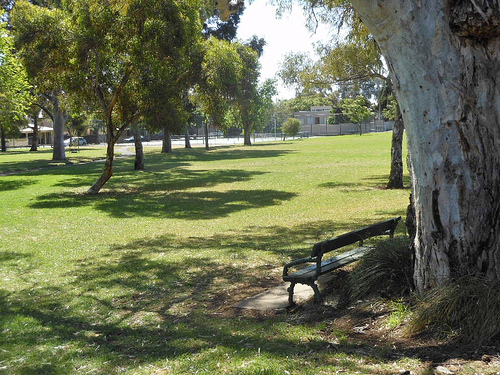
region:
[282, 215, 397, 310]
wood and wrought iron bench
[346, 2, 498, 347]
tree with white bark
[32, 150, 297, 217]
shadows cast by trees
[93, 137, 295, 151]
tennis court in the background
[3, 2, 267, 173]
clump of trees in the park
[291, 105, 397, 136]
office building in the background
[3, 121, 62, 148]
a home near the park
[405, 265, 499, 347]
wild grass growing near the base of the tree.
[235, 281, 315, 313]
cement footrest in front of the bench.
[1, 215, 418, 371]
more shadows cast by trees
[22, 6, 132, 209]
green leaves on tree in the park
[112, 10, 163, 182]
green leaves on tree in the park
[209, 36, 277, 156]
green leaves on tree in the park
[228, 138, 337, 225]
green grass in city park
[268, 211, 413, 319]
wooden bench on city park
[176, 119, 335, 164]
tennis court in city park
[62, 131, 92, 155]
silver car parked in parking lot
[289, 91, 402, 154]
white building in city park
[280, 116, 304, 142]
green leaves on tree in the park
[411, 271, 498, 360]
plant in city park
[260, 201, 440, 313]
Bench in front of tree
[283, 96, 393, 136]
Building is brown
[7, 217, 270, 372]
Shadow cast on green grass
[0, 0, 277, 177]
Trees in the field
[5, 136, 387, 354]
Green grass cover the field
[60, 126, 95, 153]
Car on a road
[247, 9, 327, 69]
Sky is white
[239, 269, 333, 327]
Bench is fixed with cement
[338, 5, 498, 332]
Trunk behind the bench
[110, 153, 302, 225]
Shadow cast on green grass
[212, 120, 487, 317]
bench underneath huge tree trunk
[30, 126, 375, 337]
great expanse of lawn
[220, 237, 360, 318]
cement block in front of bench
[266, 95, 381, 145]
building with fence in distance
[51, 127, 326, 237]
shadows of trees falling across grass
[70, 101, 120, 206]
tree with bent truck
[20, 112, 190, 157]
cars and buildings beyond the trees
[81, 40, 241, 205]
trees growing in a row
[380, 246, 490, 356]
long grass at base of tree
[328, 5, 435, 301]
curving on outer edge of tree truck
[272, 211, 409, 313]
wood bench in park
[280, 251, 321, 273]
metal arm on bench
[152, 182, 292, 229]
shadow of tree on grass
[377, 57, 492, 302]
thick tree trunk behind bench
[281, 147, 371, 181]
green grass cut short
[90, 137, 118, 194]
thin bent tree trunk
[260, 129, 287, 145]
chain link fence in distance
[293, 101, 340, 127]
building beyond fence and trees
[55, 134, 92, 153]
car on edge of park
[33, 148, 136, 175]
walkway through park grass